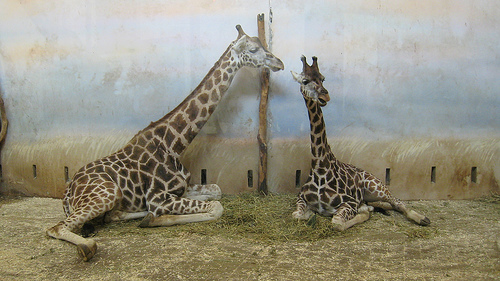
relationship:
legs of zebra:
[287, 198, 372, 233] [281, 49, 437, 234]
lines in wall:
[30, 160, 479, 185] [9, 22, 497, 222]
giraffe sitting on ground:
[294, 56, 430, 241] [0, 197, 496, 279]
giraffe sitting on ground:
[44, 23, 287, 261] [0, 197, 496, 279]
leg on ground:
[138, 196, 223, 230] [1, 195, 488, 272]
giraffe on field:
[294, 56, 430, 241] [0, 200, 499, 277]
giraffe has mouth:
[294, 56, 430, 241] [315, 93, 332, 105]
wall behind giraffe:
[2, 2, 498, 196] [44, 23, 287, 261]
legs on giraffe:
[44, 170, 226, 263] [46, 23, 286, 258]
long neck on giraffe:
[296, 102, 340, 164] [294, 56, 430, 241]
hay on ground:
[213, 188, 335, 240] [54, 242, 479, 279]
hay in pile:
[211, 181, 339, 248] [213, 180, 339, 247]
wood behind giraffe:
[253, 91, 270, 181] [70, 36, 247, 251]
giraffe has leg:
[46, 23, 286, 258] [37, 185, 122, 265]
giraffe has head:
[46, 23, 286, 258] [229, 24, 288, 74]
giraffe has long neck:
[46, 23, 286, 258] [150, 57, 251, 150]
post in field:
[382, 165, 392, 187] [5, 179, 494, 277]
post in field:
[429, 163, 437, 180] [5, 179, 494, 277]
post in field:
[470, 163, 479, 184] [5, 179, 494, 277]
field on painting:
[5, 179, 494, 277] [8, 13, 483, 199]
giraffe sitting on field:
[46, 23, 286, 258] [0, 200, 499, 277]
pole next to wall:
[251, 8, 277, 192] [2, 2, 498, 196]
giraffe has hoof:
[46, 23, 286, 258] [76, 242, 94, 261]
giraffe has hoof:
[294, 56, 430, 241] [403, 207, 431, 227]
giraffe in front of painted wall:
[44, 23, 287, 261] [398, 0, 486, 200]